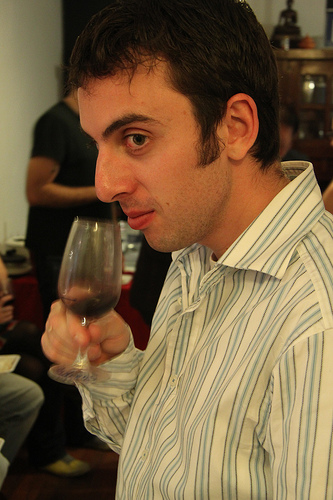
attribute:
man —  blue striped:
[40, 0, 332, 499]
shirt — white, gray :
[66, 176, 315, 476]